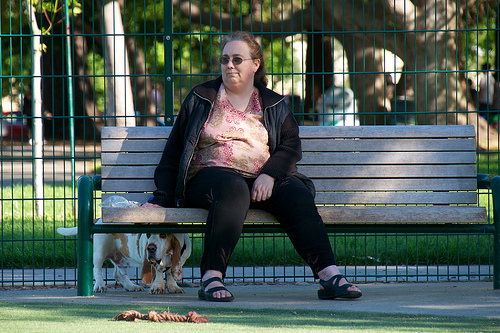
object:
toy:
[112, 306, 211, 323]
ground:
[0, 135, 500, 333]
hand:
[250, 173, 277, 204]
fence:
[1, 0, 500, 292]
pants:
[184, 165, 337, 280]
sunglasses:
[217, 55, 253, 65]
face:
[218, 39, 256, 92]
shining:
[348, 136, 428, 203]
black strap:
[202, 276, 227, 290]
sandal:
[195, 276, 235, 303]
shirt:
[184, 80, 273, 186]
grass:
[4, 146, 500, 273]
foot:
[201, 267, 233, 299]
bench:
[72, 124, 499, 298]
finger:
[266, 186, 273, 200]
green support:
[71, 175, 98, 300]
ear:
[253, 58, 261, 73]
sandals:
[316, 273, 363, 300]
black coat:
[148, 74, 317, 209]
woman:
[142, 25, 366, 302]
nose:
[227, 56, 236, 69]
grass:
[0, 299, 500, 333]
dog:
[57, 215, 193, 295]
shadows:
[149, 256, 427, 331]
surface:
[0, 265, 500, 321]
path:
[0, 264, 500, 321]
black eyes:
[158, 232, 167, 238]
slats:
[99, 123, 478, 140]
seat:
[98, 205, 489, 226]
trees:
[320, 0, 500, 157]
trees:
[79, 0, 143, 126]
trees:
[0, 0, 85, 221]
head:
[216, 29, 269, 91]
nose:
[147, 243, 157, 253]